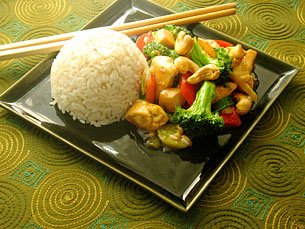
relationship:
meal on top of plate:
[50, 24, 259, 152] [0, 2, 299, 212]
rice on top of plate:
[51, 27, 148, 128] [0, 2, 299, 212]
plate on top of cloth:
[0, 2, 299, 212] [0, 1, 304, 228]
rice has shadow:
[51, 27, 148, 128] [45, 107, 136, 153]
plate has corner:
[0, 2, 299, 212] [172, 194, 200, 215]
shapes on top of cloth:
[30, 169, 109, 228] [0, 1, 304, 228]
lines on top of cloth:
[233, 188, 273, 220] [0, 1, 304, 228]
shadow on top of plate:
[45, 107, 136, 153] [0, 2, 299, 212]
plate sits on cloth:
[0, 2, 299, 212] [0, 1, 304, 228]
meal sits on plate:
[50, 24, 259, 152] [0, 2, 299, 212]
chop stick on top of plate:
[0, 2, 237, 58] [0, 2, 299, 212]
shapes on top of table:
[30, 169, 109, 228] [0, 1, 304, 228]